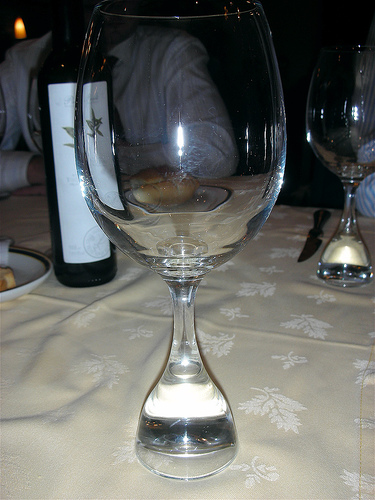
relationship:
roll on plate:
[131, 167, 195, 209] [117, 178, 235, 226]